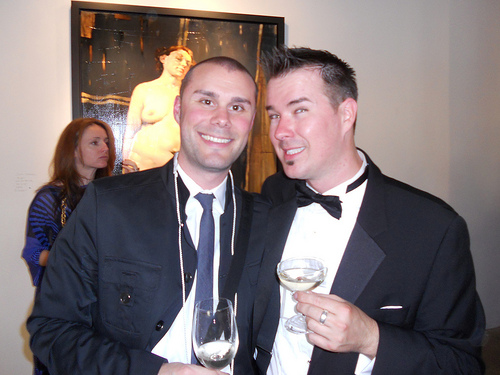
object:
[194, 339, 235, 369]
liquid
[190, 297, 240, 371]
glass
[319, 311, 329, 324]
band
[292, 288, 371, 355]
hand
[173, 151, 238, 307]
string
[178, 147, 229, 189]
neck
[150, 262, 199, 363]
handkerchief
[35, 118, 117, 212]
hair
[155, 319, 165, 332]
button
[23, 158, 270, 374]
jacket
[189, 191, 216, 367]
tie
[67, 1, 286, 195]
picture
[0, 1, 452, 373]
wall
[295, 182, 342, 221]
bow tie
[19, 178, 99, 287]
outfit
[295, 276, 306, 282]
olive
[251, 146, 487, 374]
suit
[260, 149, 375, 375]
shirt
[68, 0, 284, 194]
frame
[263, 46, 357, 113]
hair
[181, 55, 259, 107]
hair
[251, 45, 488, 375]
man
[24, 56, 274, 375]
man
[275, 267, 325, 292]
liquid